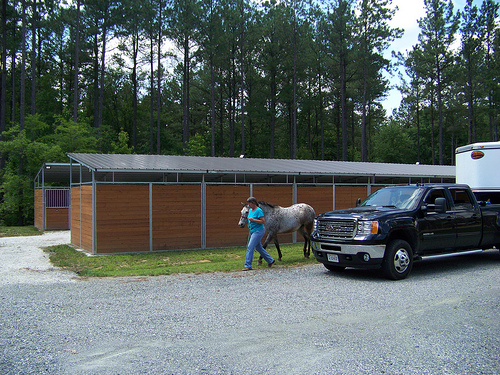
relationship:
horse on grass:
[234, 196, 319, 261] [45, 242, 320, 275]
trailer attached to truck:
[453, 140, 499, 197] [306, 181, 499, 278]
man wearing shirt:
[241, 198, 276, 272] [242, 211, 263, 238]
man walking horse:
[241, 195, 273, 270] [237, 196, 316, 266]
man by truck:
[241, 195, 273, 270] [298, 175, 499, 280]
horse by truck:
[237, 196, 316, 266] [298, 175, 499, 280]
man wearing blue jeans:
[241, 198, 276, 272] [242, 228, 274, 269]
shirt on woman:
[240, 211, 265, 226] [229, 158, 276, 280]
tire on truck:
[384, 245, 410, 287] [330, 176, 495, 263]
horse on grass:
[237, 196, 316, 266] [220, 252, 250, 271]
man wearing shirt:
[241, 198, 276, 272] [235, 202, 270, 238]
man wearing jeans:
[241, 198, 276, 272] [247, 227, 272, 264]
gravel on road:
[0, 249, 499, 374] [0, 226, 498, 373]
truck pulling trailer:
[306, 181, 499, 278] [454, 140, 499, 191]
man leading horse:
[241, 198, 276, 272] [265, 191, 362, 268]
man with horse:
[241, 198, 276, 272] [235, 192, 319, 239]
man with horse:
[241, 198, 276, 272] [236, 198, 316, 263]